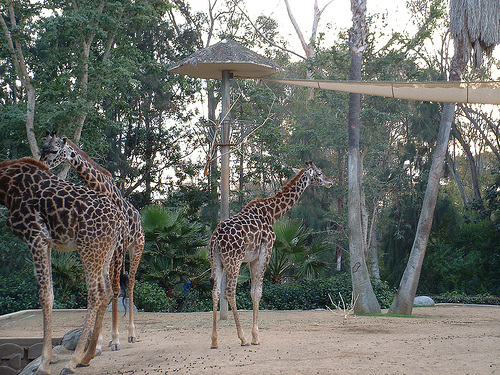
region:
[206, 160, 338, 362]
A giraffe facing away from the camera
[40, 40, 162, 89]
Tree branches with green leaves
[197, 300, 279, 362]
Legs of giraffe on the ground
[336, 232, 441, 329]
A pair of tree trunks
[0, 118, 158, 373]
two giraffes standing side by side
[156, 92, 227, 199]
A clear sky peaking through the tree branches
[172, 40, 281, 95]
A bamboo umbrella for shade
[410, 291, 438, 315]
A rock near the tree trunk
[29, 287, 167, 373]
Two pairs of giraffe legs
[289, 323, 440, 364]
A sandy beige ground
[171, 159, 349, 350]
brown and beige giraffe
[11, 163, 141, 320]
brown and beige giraffe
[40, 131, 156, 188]
giraffe standing next to another giraffe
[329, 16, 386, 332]
tall tree next to a giraffe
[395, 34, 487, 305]
tall tree next to shrubs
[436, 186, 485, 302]
shrubs in a wooded area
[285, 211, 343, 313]
shrubs near a tree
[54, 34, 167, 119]
tall trees in a wooded area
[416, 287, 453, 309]
rock in the sand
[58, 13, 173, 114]
tall trees in wooded area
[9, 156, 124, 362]
tan and brown spotted giraffe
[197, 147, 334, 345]
tan and brown spotted giraffe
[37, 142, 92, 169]
tan and brown spotted giraffe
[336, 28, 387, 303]
gray tree trunk in enclosure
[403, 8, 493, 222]
gray palm tree trunk in enclosure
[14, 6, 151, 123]
gray trees with green leaves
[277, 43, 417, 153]
gray trees with green leaves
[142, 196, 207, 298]
gray bushes with green leaves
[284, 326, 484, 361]
tan dirt in giraffe enclosure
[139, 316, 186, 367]
tan dirt in giraffe enclosure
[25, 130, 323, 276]
Three giraffes.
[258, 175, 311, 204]
The giraffe has a long neck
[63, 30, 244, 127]
Green trees in the background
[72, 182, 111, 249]
This giraffe has brown spots.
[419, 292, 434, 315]
a white rock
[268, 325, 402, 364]
The ground is brown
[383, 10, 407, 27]
A white sky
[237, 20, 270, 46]
A tree branch.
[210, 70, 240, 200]
A long beam that stands above the giraffe.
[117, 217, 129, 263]
The small tail of a giraffe.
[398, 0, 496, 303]
Tall and old palm tree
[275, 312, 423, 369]
Ground made of tan sand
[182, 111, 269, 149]
Feeding basket for giraffes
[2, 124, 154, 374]
Giraffes looking down at something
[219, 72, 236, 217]
Steel pole supporting dome lid and feeding basket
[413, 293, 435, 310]
Round, large, and gray rock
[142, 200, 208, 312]
Giant green fern foliage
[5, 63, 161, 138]
Forest of very tall green leafed trees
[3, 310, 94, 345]
Concrete framing like box to enclose sand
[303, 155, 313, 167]
Two black horns on zebra's horns